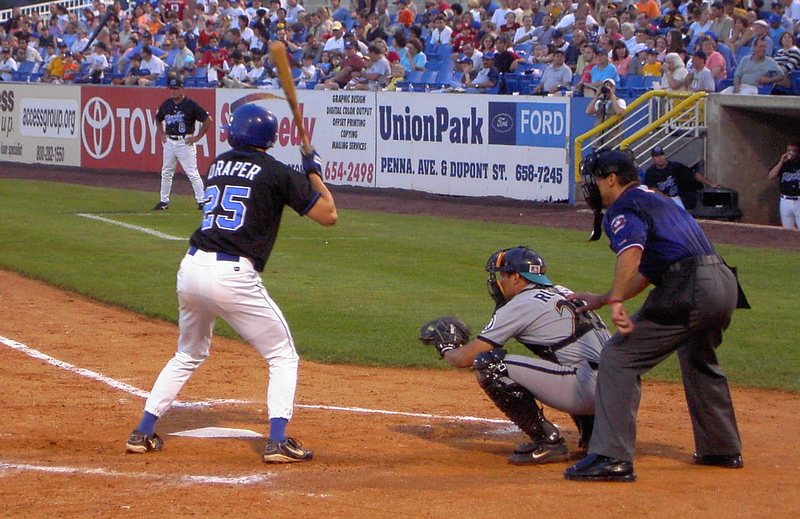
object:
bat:
[270, 40, 313, 153]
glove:
[299, 145, 322, 181]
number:
[199, 185, 249, 232]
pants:
[143, 246, 301, 422]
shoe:
[263, 437, 312, 463]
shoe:
[126, 430, 164, 453]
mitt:
[418, 315, 470, 354]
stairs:
[574, 90, 704, 205]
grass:
[0, 177, 800, 394]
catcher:
[421, 244, 613, 465]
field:
[0, 0, 800, 519]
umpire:
[567, 150, 750, 481]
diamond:
[167, 426, 264, 437]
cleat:
[507, 437, 570, 464]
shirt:
[188, 148, 322, 271]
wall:
[0, 81, 658, 201]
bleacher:
[375, 92, 569, 203]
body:
[153, 79, 215, 211]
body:
[126, 103, 336, 463]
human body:
[126, 245, 312, 462]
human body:
[420, 245, 613, 368]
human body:
[565, 145, 739, 336]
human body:
[473, 341, 599, 467]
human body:
[574, 148, 640, 208]